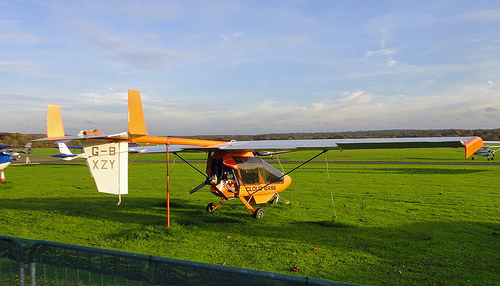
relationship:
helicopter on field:
[11, 89, 487, 228] [2, 117, 500, 283]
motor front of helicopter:
[182, 156, 235, 205] [11, 89, 487, 228]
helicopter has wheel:
[11, 89, 487, 228] [253, 209, 268, 224]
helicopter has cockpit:
[11, 89, 487, 228] [232, 153, 282, 191]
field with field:
[2, 120, 495, 283] [2, 117, 500, 283]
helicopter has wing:
[11, 89, 487, 228] [129, 82, 490, 162]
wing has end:
[129, 82, 490, 162] [125, 86, 145, 139]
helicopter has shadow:
[11, 89, 487, 228] [3, 184, 414, 257]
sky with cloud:
[2, 1, 499, 141] [72, 75, 498, 128]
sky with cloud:
[2, 1, 499, 141] [340, 31, 500, 78]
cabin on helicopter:
[198, 151, 294, 211] [11, 89, 487, 228]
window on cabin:
[230, 152, 289, 187] [198, 151, 294, 211]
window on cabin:
[238, 153, 283, 187] [198, 151, 294, 211]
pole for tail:
[164, 144, 172, 230] [32, 86, 226, 152]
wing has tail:
[129, 82, 490, 162] [98, 82, 159, 141]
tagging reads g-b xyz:
[78, 131, 131, 211] [89, 144, 117, 173]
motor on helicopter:
[184, 163, 232, 205] [43, 89, 483, 227]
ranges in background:
[4, 126, 500, 149] [5, 7, 500, 213]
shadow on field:
[3, 184, 414, 257] [2, 117, 500, 283]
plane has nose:
[0, 147, 19, 183] [1, 154, 15, 169]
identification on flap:
[89, 130, 128, 198] [34, 132, 130, 145]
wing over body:
[129, 82, 490, 162] [173, 147, 296, 231]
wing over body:
[26, 103, 129, 148] [173, 147, 296, 231]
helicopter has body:
[11, 89, 487, 228] [173, 147, 296, 231]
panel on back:
[210, 171, 223, 183] [202, 153, 244, 207]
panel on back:
[210, 156, 223, 164] [202, 153, 244, 207]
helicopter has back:
[11, 89, 487, 228] [202, 153, 244, 207]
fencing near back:
[1, 230, 427, 280] [202, 153, 244, 207]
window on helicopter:
[238, 153, 283, 187] [11, 89, 487, 228]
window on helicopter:
[230, 152, 289, 187] [11, 89, 487, 228]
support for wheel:
[237, 195, 255, 214] [253, 209, 268, 224]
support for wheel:
[215, 199, 229, 212] [250, 206, 268, 224]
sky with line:
[2, 1, 499, 141] [79, 84, 498, 137]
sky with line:
[2, 1, 499, 141] [329, 40, 498, 85]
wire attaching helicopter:
[319, 150, 340, 223] [11, 89, 487, 228]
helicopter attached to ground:
[11, 89, 487, 228] [2, 120, 495, 283]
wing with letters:
[86, 132, 130, 199] [90, 144, 115, 169]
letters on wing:
[90, 144, 115, 169] [86, 132, 130, 199]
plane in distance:
[0, 147, 19, 183] [5, 7, 500, 213]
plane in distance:
[49, 138, 150, 164] [5, 7, 500, 213]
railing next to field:
[3, 228, 403, 281] [2, 120, 495, 283]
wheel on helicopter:
[253, 209, 268, 224] [11, 89, 487, 228]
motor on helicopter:
[182, 156, 235, 205] [11, 89, 487, 228]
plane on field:
[49, 138, 150, 164] [2, 120, 495, 283]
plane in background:
[49, 138, 150, 164] [5, 7, 500, 213]